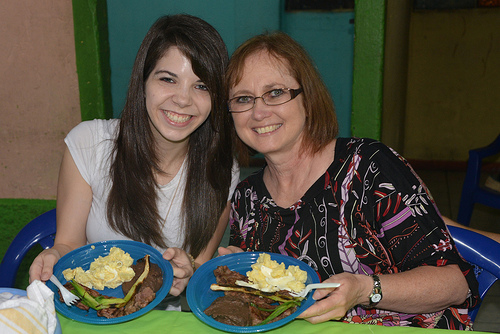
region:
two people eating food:
[70, 15, 429, 332]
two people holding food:
[23, 24, 418, 331]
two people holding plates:
[15, 20, 452, 332]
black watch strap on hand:
[368, 270, 384, 291]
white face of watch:
[365, 291, 385, 301]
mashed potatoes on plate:
[271, 259, 288, 269]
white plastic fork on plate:
[285, 280, 350, 300]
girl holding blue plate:
[20, 25, 243, 331]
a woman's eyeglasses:
[225, 78, 302, 118]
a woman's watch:
[364, 268, 384, 310]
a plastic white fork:
[47, 273, 83, 308]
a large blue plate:
[186, 253, 321, 333]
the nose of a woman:
[251, 94, 272, 121]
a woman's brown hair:
[221, 29, 346, 163]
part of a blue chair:
[0, 213, 66, 288]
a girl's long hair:
[103, 12, 237, 264]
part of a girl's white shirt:
[59, 119, 231, 255]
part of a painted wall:
[0, 8, 58, 192]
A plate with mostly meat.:
[190, 246, 327, 331]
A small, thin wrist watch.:
[369, 270, 384, 312]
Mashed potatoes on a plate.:
[243, 251, 312, 296]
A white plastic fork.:
[49, 276, 79, 304]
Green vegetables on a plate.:
[83, 285, 118, 309]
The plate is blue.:
[183, 272, 211, 297]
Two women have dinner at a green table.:
[20, 23, 478, 333]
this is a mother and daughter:
[173, 110, 346, 293]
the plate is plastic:
[191, 277, 203, 293]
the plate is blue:
[185, 299, 227, 326]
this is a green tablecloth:
[151, 315, 168, 327]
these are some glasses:
[248, 39, 325, 141]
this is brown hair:
[96, 141, 153, 186]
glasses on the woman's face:
[228, 86, 300, 112]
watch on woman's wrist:
[366, 274, 382, 311]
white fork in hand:
[296, 281, 342, 299]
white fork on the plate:
[51, 272, 78, 307]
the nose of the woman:
[252, 103, 270, 123]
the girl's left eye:
[192, 83, 208, 90]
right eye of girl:
[157, 76, 176, 85]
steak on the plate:
[114, 259, 160, 320]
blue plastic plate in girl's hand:
[45, 237, 170, 325]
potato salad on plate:
[249, 252, 312, 293]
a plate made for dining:
[193, 246, 313, 329]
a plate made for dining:
[45, 236, 166, 327]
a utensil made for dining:
[44, 271, 84, 309]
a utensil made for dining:
[292, 273, 335, 298]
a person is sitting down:
[25, 26, 235, 284]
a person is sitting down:
[195, 27, 475, 325]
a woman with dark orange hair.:
[222, 33, 454, 329]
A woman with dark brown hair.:
[65, 28, 252, 270]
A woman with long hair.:
[57, 27, 243, 265]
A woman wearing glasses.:
[220, 36, 462, 323]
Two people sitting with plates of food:
[35, 33, 436, 324]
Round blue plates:
[46, 228, 323, 332]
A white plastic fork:
[48, 271, 80, 313]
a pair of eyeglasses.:
[231, 84, 302, 113]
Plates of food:
[37, 237, 316, 332]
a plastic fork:
[285, 276, 355, 302]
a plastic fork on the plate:
[30, 266, 87, 311]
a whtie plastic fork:
[330, 270, 382, 315]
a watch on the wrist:
[355, 267, 386, 314]